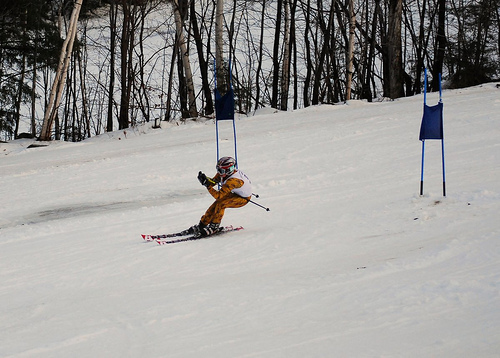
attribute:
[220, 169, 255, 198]
vest — white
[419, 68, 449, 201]
flag — blue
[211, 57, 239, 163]
flag — blue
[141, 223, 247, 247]
skis — skiis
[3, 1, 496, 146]
trees — green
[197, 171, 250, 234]
snow suit — orange, covered, white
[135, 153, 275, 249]
skier — downhill slalom, skiing, racing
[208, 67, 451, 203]
gate — blue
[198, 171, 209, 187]
gloves — black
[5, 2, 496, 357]
landscape — snowy